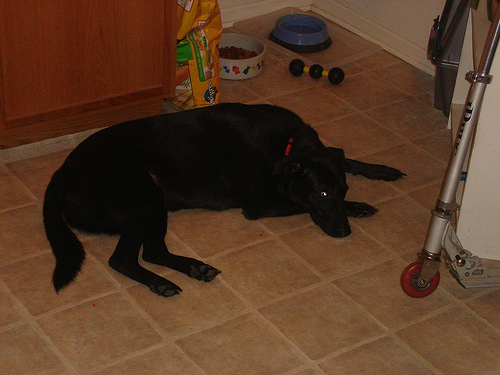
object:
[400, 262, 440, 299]
wheel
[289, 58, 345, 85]
toy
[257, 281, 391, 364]
tile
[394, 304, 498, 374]
tile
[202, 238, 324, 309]
tile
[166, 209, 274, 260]
tile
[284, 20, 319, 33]
water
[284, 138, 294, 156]
collar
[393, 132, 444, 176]
ground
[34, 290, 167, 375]
tile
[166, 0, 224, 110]
food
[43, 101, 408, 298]
black dog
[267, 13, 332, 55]
bowl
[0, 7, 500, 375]
floor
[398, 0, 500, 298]
scooter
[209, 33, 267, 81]
bowl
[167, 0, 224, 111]
bag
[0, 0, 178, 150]
cabinet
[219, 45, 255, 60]
food